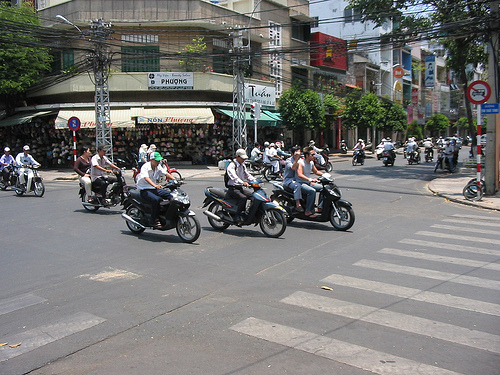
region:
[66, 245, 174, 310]
small spot on street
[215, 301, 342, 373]
broad white lines in street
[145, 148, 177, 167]
green and white cap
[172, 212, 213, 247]
black wheel on bike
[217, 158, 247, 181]
black backpack on man's back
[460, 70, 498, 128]
red and white circle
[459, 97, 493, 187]
long white line with red lines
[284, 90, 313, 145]
large green tree on sidewalk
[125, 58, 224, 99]
white sign on building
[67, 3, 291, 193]
large brown building on sidewalk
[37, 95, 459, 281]
rows of motorcyclists at intersection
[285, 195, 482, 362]
dirty lines of crosswalk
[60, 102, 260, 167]
merchandise displayed in corner store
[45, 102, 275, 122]
yellow and green awnings over store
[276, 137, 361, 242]
biker with bare arms and passenger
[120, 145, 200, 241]
biker wearing green and white cap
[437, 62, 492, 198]
red and white traffic sign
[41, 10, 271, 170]
metal structures connected to wires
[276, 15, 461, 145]
commercial street lined with trees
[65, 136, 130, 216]
man and woman on black motorcycle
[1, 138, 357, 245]
Group of people riding motorcycles.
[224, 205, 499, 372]
Crosswalk.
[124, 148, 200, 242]
Man in a green baseball cap on a motorcycle.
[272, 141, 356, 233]
Two people on a motorcycle.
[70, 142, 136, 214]
Man and a woman on a motorcycle.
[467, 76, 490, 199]
Traffic sign.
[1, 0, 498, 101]
Utility lines.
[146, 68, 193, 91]
Sign on building.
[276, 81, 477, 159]
Line of leafy green trees on the sidewalk.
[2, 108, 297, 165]
Store with a yellow awning.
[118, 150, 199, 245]
A man on a motor cycle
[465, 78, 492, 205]
A red and white sign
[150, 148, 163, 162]
A green and white cap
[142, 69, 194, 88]
A white and black sign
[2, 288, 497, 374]
A paved road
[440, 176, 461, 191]
A sidewalk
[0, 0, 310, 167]
A large beige building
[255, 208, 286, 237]
Wheel of a motor cycle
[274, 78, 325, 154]
A tree with green leaves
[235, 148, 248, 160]
A white cap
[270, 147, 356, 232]
the lead motorcycle with two riders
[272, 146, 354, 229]
two riders with no helmets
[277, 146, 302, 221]
a passenger wearing sunglasses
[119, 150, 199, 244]
a rider in a green and white cap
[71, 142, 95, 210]
a passenger in brown top and white pants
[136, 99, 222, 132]
an awning on a store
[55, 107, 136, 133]
an awning on a store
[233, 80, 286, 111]
a promotional banner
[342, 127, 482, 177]
cyclist going in two directions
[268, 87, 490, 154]
trees in planters